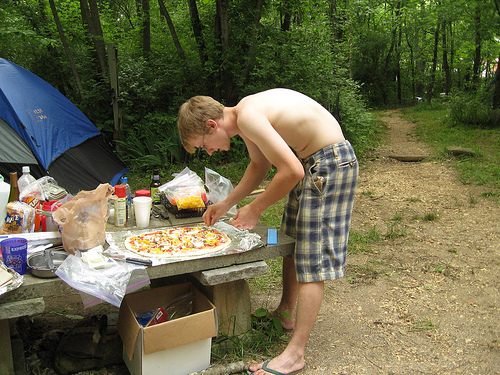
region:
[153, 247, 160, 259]
Big pizza on top of a table.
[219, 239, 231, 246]
Big pizza on top of a table.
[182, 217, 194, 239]
Big pizza on top of a table.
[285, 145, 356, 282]
Plaid shorts on man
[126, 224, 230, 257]
Pizza lying on table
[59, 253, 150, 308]
Clear zip lock bags on table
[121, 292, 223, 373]
Cardboard box under table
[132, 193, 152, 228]
White cup on table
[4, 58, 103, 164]
Blue and white tent on ground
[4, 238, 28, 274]
Blue cup on table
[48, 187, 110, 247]
Tan plastic grocery bag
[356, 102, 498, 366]
Tan dirt path in woods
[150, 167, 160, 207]
Brown glass bottle with yellow label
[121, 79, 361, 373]
A man bent over making a pizza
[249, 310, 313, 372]
A pair of flip flop shoes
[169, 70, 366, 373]
A man not wearing a shirt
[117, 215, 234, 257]
A round uncooked pizza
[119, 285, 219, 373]
A cardboard box with items inside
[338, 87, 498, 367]
A dirt trail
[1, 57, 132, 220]
A blue, black, and grey tent.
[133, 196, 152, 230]
A white styrofoam cup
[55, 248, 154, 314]
Plastic ziplock bags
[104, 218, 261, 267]
Aluminum foil under a pizza.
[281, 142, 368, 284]
a man's long shorts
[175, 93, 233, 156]
a man's short cut hair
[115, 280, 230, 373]
a large brown and white box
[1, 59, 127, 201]
part of a large blue, gray and black tent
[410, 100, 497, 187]
a section of green grass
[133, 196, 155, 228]
a white styrofoam cup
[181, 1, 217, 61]
part of a tree branch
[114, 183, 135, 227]
a tall spray can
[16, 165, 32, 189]
part of a bottle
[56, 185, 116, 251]
a brown plastic bag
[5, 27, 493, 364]
Some people are doing some camping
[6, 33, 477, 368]
A person is getting some food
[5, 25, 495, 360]
A person is at a campsite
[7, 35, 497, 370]
A person is wearing short pants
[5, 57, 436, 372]
A person is not wearing a shirt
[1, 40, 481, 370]
The person is close to a trail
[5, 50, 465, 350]
A person is close to a tent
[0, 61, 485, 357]
The person has set up a campsite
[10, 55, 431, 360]
The person is having a great time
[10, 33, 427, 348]
The person is enjoying their day